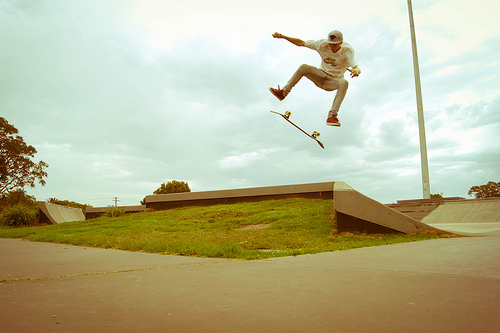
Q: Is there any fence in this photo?
A: No, there are no fences.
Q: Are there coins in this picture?
A: No, there are no coins.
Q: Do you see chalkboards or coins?
A: No, there are no coins or chalkboards.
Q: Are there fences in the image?
A: No, there are no fences.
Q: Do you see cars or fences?
A: No, there are no fences or cars.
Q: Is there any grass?
A: Yes, there is grass.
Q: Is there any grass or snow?
A: Yes, there is grass.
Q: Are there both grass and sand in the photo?
A: No, there is grass but no sand.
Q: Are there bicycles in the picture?
A: No, there are no bicycles.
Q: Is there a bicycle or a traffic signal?
A: No, there are no bicycles or traffic lights.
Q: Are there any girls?
A: No, there are no girls.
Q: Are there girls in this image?
A: No, there are no girls.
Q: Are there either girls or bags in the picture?
A: No, there are no girls or bags.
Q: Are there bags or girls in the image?
A: No, there are no girls or bags.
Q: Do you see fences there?
A: No, there are no fences.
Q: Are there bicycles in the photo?
A: No, there are no bicycles.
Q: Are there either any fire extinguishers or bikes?
A: No, there are no bikes or fire extinguishers.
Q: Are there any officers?
A: No, there are no officers.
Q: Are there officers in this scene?
A: No, there are no officers.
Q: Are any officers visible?
A: No, there are no officers.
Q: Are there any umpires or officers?
A: No, there are no officers or umpires.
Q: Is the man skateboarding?
A: Yes, the man is skateboarding.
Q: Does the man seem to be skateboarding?
A: Yes, the man is skateboarding.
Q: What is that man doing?
A: The man is skateboarding.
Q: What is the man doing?
A: The man is skateboarding.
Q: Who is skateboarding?
A: The man is skateboarding.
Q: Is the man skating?
A: No, the man is skateboarding.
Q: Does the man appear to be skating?
A: No, the man is skateboarding.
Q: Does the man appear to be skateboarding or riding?
A: The man is skateboarding.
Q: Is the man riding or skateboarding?
A: The man is skateboarding.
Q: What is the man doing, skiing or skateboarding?
A: The man is skateboarding.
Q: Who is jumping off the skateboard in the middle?
A: The man is jumping off the skateboard.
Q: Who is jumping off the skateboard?
A: The man is jumping off the skateboard.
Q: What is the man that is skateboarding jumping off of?
A: The man is jumping off the skateboard.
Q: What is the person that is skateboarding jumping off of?
A: The man is jumping off the skateboard.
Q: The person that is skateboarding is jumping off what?
A: The man is jumping off the skateboard.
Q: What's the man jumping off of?
A: The man is jumping off the skateboard.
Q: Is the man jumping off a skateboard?
A: Yes, the man is jumping off a skateboard.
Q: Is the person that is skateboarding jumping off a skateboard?
A: Yes, the man is jumping off a skateboard.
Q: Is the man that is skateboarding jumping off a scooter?
A: No, the man is jumping off a skateboard.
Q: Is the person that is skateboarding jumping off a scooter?
A: No, the man is jumping off a skateboard.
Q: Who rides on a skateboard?
A: The man rides on a skateboard.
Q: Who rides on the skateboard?
A: The man rides on a skateboard.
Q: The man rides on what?
A: The man rides on a skateboard.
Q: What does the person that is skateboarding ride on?
A: The man rides on a skateboard.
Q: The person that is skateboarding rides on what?
A: The man rides on a skateboard.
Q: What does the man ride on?
A: The man rides on a skateboard.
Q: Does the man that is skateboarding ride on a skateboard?
A: Yes, the man rides on a skateboard.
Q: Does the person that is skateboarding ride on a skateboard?
A: Yes, the man rides on a skateboard.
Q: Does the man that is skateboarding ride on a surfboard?
A: No, the man rides on a skateboard.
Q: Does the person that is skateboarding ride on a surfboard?
A: No, the man rides on a skateboard.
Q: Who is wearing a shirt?
A: The man is wearing a shirt.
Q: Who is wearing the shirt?
A: The man is wearing a shirt.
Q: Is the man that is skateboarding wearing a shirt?
A: Yes, the man is wearing a shirt.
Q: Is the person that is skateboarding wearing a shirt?
A: Yes, the man is wearing a shirt.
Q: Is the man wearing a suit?
A: No, the man is wearing a shirt.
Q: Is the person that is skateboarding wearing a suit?
A: No, the man is wearing a shirt.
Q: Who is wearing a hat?
A: The man is wearing a hat.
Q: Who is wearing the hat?
A: The man is wearing a hat.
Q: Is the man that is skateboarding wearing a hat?
A: Yes, the man is wearing a hat.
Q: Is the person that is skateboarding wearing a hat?
A: Yes, the man is wearing a hat.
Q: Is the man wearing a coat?
A: No, the man is wearing a hat.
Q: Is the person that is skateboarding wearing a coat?
A: No, the man is wearing a hat.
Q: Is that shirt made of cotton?
A: Yes, the shirt is made of cotton.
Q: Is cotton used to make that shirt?
A: Yes, the shirt is made of cotton.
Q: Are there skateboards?
A: Yes, there is a skateboard.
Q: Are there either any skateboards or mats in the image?
A: Yes, there is a skateboard.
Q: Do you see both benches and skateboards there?
A: No, there is a skateboard but no benches.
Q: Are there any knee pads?
A: No, there are no knee pads.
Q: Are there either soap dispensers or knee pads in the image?
A: No, there are no knee pads or soap dispensers.